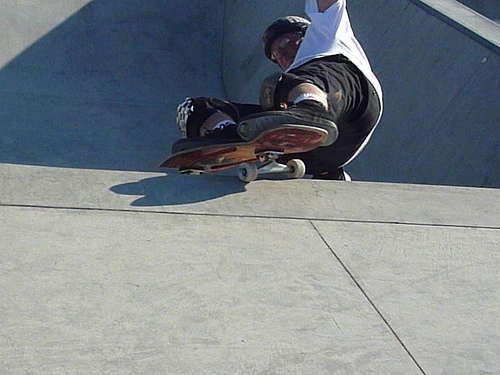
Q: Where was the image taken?
A: It was taken at the skate park.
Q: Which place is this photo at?
A: It is at the skate park.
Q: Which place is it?
A: It is a skate park.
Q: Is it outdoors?
A: Yes, it is outdoors.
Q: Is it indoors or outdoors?
A: It is outdoors.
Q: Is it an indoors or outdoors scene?
A: It is outdoors.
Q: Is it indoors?
A: No, it is outdoors.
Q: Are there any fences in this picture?
A: No, there are no fences.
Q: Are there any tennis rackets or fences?
A: No, there are no fences or tennis rackets.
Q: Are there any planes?
A: No, there are no planes.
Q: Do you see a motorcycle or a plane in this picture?
A: No, there are no airplanes or motorcycles.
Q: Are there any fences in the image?
A: No, there are no fences.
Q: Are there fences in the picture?
A: No, there are no fences.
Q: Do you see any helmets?
A: Yes, there is a helmet.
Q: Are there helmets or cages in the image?
A: Yes, there is a helmet.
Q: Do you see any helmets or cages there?
A: Yes, there is a helmet.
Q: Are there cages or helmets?
A: Yes, there is a helmet.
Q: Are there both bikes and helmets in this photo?
A: No, there is a helmet but no bikes.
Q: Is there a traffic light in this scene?
A: No, there are no traffic lights.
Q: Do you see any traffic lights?
A: No, there are no traffic lights.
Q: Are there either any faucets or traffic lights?
A: No, there are no traffic lights or faucets.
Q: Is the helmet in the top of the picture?
A: Yes, the helmet is in the top of the image.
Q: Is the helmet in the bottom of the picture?
A: No, the helmet is in the top of the image.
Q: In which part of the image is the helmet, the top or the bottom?
A: The helmet is in the top of the image.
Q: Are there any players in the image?
A: No, there are no players.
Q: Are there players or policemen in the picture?
A: No, there are no players or policemen.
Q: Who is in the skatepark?
A: The boy is in the skatepark.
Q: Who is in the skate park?
A: The boy is in the skatepark.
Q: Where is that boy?
A: The boy is in the skatepark.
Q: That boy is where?
A: The boy is in the skatepark.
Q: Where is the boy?
A: The boy is in the skatepark.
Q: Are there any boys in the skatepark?
A: Yes, there is a boy in the skatepark.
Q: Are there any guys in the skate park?
A: No, there is a boy in the skate park.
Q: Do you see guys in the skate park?
A: No, there is a boy in the skate park.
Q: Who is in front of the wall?
A: The boy is in front of the wall.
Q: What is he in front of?
A: The boy is in front of the wall.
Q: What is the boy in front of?
A: The boy is in front of the wall.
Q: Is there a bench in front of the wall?
A: No, there is a boy in front of the wall.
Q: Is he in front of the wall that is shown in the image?
A: Yes, the boy is in front of the wall.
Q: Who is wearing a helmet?
A: The boy is wearing a helmet.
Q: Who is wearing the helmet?
A: The boy is wearing a helmet.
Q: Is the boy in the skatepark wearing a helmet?
A: Yes, the boy is wearing a helmet.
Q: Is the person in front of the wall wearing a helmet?
A: Yes, the boy is wearing a helmet.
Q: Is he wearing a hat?
A: No, the boy is wearing a helmet.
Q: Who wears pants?
A: The boy wears pants.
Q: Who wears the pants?
A: The boy wears pants.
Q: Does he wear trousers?
A: Yes, the boy wears trousers.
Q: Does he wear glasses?
A: No, the boy wears trousers.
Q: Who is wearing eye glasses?
A: The boy is wearing eye glasses.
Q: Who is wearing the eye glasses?
A: The boy is wearing eye glasses.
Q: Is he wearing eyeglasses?
A: Yes, the boy is wearing eyeglasses.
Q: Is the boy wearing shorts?
A: No, the boy is wearing eyeglasses.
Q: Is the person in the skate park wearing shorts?
A: No, the boy is wearing eyeglasses.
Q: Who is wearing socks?
A: The boy is wearing socks.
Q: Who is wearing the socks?
A: The boy is wearing socks.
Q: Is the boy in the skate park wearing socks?
A: Yes, the boy is wearing socks.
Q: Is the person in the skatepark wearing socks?
A: Yes, the boy is wearing socks.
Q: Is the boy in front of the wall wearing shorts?
A: No, the boy is wearing socks.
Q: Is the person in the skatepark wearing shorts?
A: No, the boy is wearing socks.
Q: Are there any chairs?
A: No, there are no chairs.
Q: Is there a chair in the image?
A: No, there are no chairs.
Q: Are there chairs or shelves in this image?
A: No, there are no chairs or shelves.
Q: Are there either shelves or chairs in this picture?
A: No, there are no chairs or shelves.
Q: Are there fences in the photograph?
A: No, there are no fences.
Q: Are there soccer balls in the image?
A: No, there are no soccer balls.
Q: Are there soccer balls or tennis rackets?
A: No, there are no soccer balls or tennis rackets.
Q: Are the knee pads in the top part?
A: Yes, the knee pads are in the top of the image.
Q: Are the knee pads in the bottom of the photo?
A: No, the knee pads are in the top of the image.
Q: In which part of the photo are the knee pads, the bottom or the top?
A: The knee pads are in the top of the image.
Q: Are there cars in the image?
A: No, there are no cars.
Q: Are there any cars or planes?
A: No, there are no cars or planes.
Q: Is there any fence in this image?
A: No, there are no fences.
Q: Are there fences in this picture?
A: No, there are no fences.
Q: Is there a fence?
A: No, there are no fences.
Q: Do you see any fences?
A: No, there are no fences.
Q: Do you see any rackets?
A: No, there are no rackets.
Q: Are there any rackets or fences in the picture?
A: No, there are no rackets or fences.